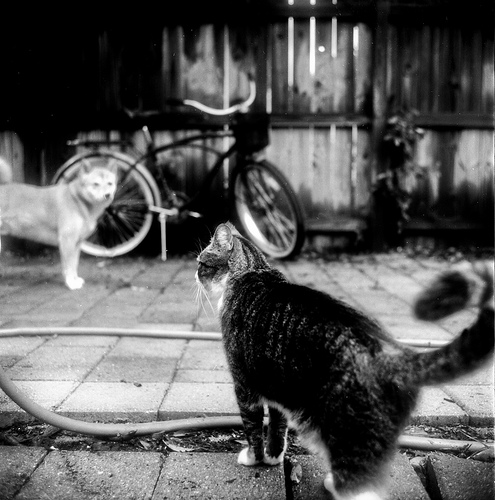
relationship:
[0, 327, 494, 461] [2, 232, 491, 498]
hose on top of patio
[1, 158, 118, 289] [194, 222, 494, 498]
dog looking at cat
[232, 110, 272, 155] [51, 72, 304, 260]
basket in front of bike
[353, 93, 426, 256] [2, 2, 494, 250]
plant against fence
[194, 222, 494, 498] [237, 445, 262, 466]
cat has paw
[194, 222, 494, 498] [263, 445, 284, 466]
cat has paw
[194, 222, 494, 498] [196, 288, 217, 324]
cat has whiskers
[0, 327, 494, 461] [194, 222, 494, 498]
hose in from of cat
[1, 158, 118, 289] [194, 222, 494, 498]
dog across cat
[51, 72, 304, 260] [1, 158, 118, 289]
bike behind dog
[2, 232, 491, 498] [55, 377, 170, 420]
patio has brick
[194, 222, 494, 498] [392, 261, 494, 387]
cat has tail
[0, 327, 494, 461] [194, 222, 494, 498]
hose in front of cat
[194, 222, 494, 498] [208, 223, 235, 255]
cat has ear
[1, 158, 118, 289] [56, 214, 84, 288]
dog has front leg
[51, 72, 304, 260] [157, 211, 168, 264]
bike has kickstand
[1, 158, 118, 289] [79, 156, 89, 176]
dog has ear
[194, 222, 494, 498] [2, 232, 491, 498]
cat on top of patio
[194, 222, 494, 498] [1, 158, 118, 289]
cat seeing dog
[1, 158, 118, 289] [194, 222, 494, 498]
dog seeing cat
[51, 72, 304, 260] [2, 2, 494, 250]
bike against fence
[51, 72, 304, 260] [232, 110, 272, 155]
bike has basket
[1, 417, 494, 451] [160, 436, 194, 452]
hole has leaf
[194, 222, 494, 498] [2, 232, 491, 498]
cat standing on patio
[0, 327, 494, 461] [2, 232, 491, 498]
hose crossing patio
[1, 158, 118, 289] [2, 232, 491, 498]
dog on top of patio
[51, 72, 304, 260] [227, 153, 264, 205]
bike has fender